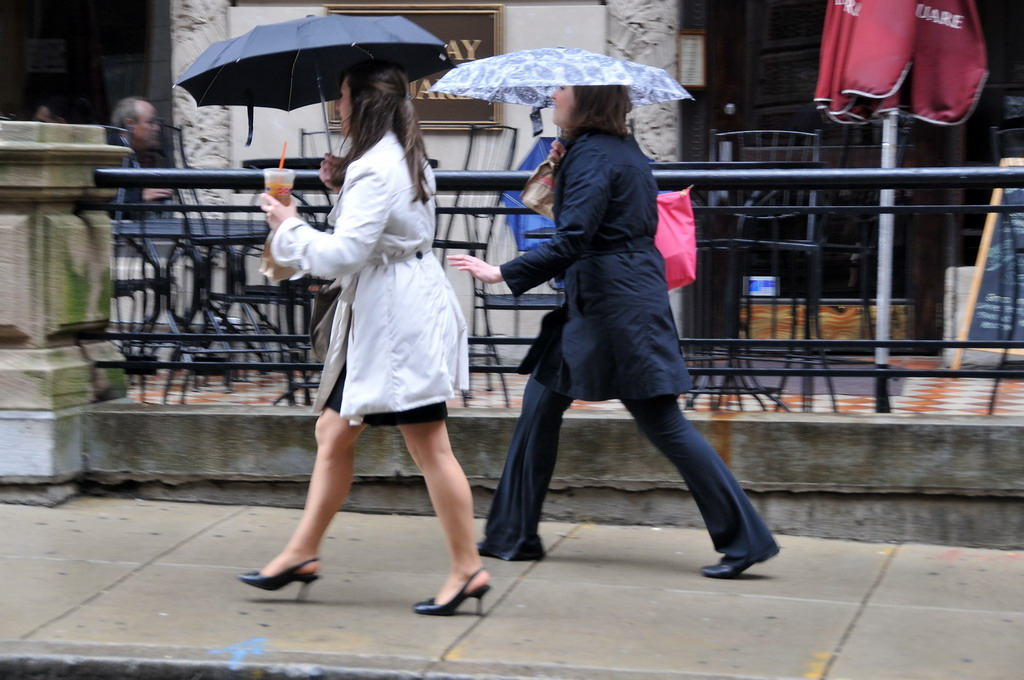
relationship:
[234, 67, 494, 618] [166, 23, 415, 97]
girl carrying umbrella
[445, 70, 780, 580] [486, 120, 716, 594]
girl in pant suit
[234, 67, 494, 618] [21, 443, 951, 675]
girl on sidewalk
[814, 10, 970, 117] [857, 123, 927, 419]
parasol on stand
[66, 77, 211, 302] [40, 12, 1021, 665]
man in eatery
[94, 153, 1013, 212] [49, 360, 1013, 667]
railing on sidewalk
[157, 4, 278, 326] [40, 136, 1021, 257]
pillar supporting railing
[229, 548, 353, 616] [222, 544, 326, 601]
shoe on foot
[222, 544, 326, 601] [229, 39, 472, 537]
foot of girl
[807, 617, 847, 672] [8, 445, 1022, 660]
line on ground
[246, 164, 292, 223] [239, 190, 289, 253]
drink in hand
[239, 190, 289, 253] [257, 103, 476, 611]
hand of girl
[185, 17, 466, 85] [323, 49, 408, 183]
umbrella over head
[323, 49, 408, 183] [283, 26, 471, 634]
head of girl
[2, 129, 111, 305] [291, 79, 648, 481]
post next to girls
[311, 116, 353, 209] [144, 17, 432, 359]
handle of object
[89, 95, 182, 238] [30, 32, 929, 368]
man in distance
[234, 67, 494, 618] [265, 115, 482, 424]
girl in a whit coat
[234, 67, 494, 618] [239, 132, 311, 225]
girl carrying a iced coffee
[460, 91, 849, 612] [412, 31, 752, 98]
girl with blue umbrella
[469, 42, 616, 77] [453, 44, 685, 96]
floral design on canopy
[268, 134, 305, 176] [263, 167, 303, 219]
red straw in coffee cup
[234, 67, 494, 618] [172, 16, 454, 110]
girl carrying an umbrella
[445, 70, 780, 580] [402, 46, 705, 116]
girl carrying an umbrella